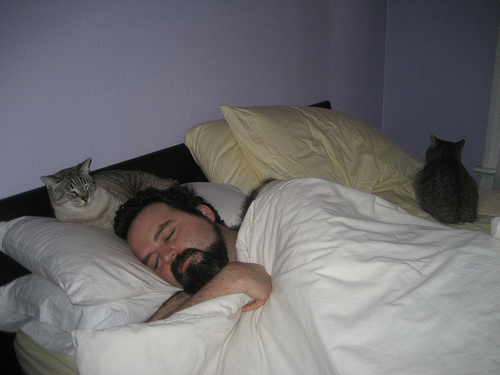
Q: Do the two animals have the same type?
A: Yes, all the animals are cats.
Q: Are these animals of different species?
A: No, all the animals are cats.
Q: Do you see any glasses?
A: No, there are no glasses.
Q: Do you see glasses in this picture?
A: No, there are no glasses.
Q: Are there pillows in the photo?
A: Yes, there are pillows.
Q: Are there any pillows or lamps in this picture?
A: Yes, there are pillows.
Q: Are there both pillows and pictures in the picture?
A: No, there are pillows but no pictures.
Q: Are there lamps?
A: No, there are no lamps.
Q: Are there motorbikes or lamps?
A: No, there are no lamps or motorbikes.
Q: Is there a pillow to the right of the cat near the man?
A: Yes, there are pillows to the right of the cat.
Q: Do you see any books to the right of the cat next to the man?
A: No, there are pillows to the right of the cat.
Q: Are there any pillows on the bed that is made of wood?
A: Yes, there are pillows on the bed.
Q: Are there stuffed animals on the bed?
A: No, there are pillows on the bed.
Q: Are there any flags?
A: No, there are no flags.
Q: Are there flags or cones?
A: No, there are no flags or cones.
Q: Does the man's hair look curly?
A: Yes, the hair is curly.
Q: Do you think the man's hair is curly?
A: Yes, the hair is curly.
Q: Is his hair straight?
A: No, the hair is curly.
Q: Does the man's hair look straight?
A: No, the hair is curly.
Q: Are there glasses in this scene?
A: No, there are no glasses.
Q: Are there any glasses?
A: No, there are no glasses.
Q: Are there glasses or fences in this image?
A: No, there are no glasses or fences.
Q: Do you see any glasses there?
A: No, there are no glasses.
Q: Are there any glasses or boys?
A: No, there are no glasses or boys.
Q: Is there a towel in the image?
A: No, there are no towels.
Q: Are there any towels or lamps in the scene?
A: No, there are no towels or lamps.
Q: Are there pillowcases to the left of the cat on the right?
A: Yes, there is a pillowcase to the left of the cat.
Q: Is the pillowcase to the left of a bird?
A: No, the pillowcase is to the left of the cat.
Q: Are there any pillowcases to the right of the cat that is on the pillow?
A: Yes, there is a pillowcase to the right of the cat.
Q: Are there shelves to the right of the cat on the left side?
A: No, there is a pillowcase to the right of the cat.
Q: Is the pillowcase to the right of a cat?
A: Yes, the pillowcase is to the right of a cat.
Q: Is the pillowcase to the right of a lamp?
A: No, the pillowcase is to the right of a cat.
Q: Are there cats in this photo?
A: Yes, there is a cat.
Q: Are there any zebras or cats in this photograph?
A: Yes, there is a cat.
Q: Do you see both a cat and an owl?
A: No, there is a cat but no owls.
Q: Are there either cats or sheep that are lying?
A: Yes, the cat is lying.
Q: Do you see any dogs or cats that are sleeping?
A: Yes, the cat is sleeping.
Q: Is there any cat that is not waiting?
A: Yes, there is a cat that is sleeping.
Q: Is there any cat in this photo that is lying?
A: Yes, there is a cat that is lying.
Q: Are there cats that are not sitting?
A: Yes, there is a cat that is lying.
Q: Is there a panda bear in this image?
A: No, there are no pandas.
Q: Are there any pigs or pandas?
A: No, there are no pandas or pigs.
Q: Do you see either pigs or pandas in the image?
A: No, there are no pandas or pigs.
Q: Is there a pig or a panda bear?
A: No, there are no pandas or pigs.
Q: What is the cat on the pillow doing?
A: The cat is lying.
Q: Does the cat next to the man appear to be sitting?
A: No, the cat is lying.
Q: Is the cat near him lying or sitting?
A: The cat is lying.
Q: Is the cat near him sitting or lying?
A: The cat is lying.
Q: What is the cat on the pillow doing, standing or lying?
A: The cat is lying.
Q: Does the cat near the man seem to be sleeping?
A: Yes, the cat is sleeping.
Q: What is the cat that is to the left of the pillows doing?
A: The cat is sleeping.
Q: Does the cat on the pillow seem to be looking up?
A: No, the cat is sleeping.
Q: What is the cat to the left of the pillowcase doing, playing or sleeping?
A: The cat is sleeping.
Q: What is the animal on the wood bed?
A: The animal is a cat.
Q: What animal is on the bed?
A: The animal is a cat.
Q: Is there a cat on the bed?
A: Yes, there is a cat on the bed.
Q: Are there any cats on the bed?
A: Yes, there is a cat on the bed.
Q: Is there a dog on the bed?
A: No, there is a cat on the bed.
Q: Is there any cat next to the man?
A: Yes, there is a cat next to the man.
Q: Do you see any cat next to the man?
A: Yes, there is a cat next to the man.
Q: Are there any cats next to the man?
A: Yes, there is a cat next to the man.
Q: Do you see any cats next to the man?
A: Yes, there is a cat next to the man.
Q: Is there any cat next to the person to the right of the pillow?
A: Yes, there is a cat next to the man.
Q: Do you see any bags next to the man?
A: No, there is a cat next to the man.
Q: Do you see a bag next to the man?
A: No, there is a cat next to the man.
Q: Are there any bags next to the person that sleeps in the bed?
A: No, there is a cat next to the man.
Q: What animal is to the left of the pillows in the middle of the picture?
A: The animal is a cat.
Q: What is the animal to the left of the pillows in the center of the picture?
A: The animal is a cat.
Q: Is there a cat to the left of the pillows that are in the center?
A: Yes, there is a cat to the left of the pillows.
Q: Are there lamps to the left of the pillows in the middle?
A: No, there is a cat to the left of the pillows.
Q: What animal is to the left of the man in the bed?
A: The animal is a cat.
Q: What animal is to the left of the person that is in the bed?
A: The animal is a cat.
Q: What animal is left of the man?
A: The animal is a cat.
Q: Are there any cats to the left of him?
A: Yes, there is a cat to the left of the man.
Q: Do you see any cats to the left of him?
A: Yes, there is a cat to the left of the man.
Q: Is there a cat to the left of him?
A: Yes, there is a cat to the left of the man.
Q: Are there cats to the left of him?
A: Yes, there is a cat to the left of the man.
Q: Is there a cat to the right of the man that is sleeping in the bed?
A: No, the cat is to the left of the man.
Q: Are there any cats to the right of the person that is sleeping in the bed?
A: No, the cat is to the left of the man.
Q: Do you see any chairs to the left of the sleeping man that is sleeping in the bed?
A: No, there is a cat to the left of the man.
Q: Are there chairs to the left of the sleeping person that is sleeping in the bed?
A: No, there is a cat to the left of the man.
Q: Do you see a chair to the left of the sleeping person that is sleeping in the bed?
A: No, there is a cat to the left of the man.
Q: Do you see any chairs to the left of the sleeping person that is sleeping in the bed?
A: No, there is a cat to the left of the man.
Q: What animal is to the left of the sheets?
A: The animal is a cat.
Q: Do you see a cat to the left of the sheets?
A: Yes, there is a cat to the left of the sheets.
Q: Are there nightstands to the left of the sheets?
A: No, there is a cat to the left of the sheets.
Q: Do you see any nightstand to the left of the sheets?
A: No, there is a cat to the left of the sheets.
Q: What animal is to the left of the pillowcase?
A: The animal is a cat.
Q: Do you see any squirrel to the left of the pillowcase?
A: No, there is a cat to the left of the pillowcase.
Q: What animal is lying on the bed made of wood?
A: The cat is lying on the bed.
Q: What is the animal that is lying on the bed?
A: The animal is a cat.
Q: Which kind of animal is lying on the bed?
A: The animal is a cat.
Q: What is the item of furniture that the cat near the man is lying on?
A: The piece of furniture is a bed.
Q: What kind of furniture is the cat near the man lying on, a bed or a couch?
A: The cat is lying on a bed.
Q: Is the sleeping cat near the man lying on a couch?
A: No, the cat is lying on the bed.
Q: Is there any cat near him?
A: Yes, there is a cat near the man.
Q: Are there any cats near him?
A: Yes, there is a cat near the man.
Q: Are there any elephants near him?
A: No, there is a cat near the man.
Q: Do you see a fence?
A: No, there are no fences.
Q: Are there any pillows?
A: Yes, there is a pillow.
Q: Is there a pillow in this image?
A: Yes, there is a pillow.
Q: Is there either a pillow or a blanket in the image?
A: Yes, there is a pillow.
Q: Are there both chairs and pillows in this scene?
A: No, there is a pillow but no chairs.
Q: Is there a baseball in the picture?
A: No, there are no baseballs.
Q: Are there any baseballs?
A: No, there are no baseballs.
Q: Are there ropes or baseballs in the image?
A: No, there are no baseballs or ropes.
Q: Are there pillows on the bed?
A: Yes, there is a pillow on the bed.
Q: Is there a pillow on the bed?
A: Yes, there is a pillow on the bed.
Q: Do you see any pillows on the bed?
A: Yes, there is a pillow on the bed.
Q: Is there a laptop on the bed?
A: No, there is a pillow on the bed.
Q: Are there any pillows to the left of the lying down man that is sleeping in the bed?
A: Yes, there is a pillow to the left of the man.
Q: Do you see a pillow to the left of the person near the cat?
A: Yes, there is a pillow to the left of the man.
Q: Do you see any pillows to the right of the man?
A: No, the pillow is to the left of the man.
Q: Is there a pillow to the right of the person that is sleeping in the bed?
A: No, the pillow is to the left of the man.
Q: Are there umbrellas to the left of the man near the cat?
A: No, there is a pillow to the left of the man.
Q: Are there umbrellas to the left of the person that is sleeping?
A: No, there is a pillow to the left of the man.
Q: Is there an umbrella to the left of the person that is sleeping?
A: No, there is a pillow to the left of the man.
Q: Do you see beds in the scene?
A: Yes, there is a bed.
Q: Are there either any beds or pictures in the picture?
A: Yes, there is a bed.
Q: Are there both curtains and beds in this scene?
A: No, there is a bed but no curtains.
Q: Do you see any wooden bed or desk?
A: Yes, there is a wood bed.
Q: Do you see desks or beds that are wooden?
A: Yes, the bed is wooden.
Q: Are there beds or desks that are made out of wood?
A: Yes, the bed is made of wood.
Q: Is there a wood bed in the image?
A: Yes, there is a wood bed.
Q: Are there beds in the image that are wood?
A: Yes, there is a wood bed.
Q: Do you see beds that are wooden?
A: Yes, there is a bed that is wooden.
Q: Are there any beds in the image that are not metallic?
A: Yes, there is a wooden bed.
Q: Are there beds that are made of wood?
A: Yes, there is a bed that is made of wood.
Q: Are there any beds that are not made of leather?
A: Yes, there is a bed that is made of wood.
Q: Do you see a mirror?
A: No, there are no mirrors.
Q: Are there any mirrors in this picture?
A: No, there are no mirrors.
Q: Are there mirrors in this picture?
A: No, there are no mirrors.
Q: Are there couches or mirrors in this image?
A: No, there are no mirrors or couches.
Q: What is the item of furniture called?
A: The piece of furniture is a bed.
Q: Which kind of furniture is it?
A: The piece of furniture is a bed.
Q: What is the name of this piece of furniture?
A: This is a bed.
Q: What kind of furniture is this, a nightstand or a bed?
A: This is a bed.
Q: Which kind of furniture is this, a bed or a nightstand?
A: This is a bed.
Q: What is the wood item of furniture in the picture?
A: The piece of furniture is a bed.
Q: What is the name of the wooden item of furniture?
A: The piece of furniture is a bed.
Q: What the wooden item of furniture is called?
A: The piece of furniture is a bed.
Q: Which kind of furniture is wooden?
A: The furniture is a bed.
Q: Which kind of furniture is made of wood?
A: The furniture is a bed.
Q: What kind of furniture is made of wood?
A: The furniture is a bed.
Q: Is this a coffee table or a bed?
A: This is a bed.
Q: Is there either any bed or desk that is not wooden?
A: No, there is a bed but it is wooden.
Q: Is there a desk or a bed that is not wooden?
A: No, there is a bed but it is wooden.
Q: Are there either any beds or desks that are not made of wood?
A: No, there is a bed but it is made of wood.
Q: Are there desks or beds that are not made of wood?
A: No, there is a bed but it is made of wood.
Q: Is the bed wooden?
A: Yes, the bed is wooden.